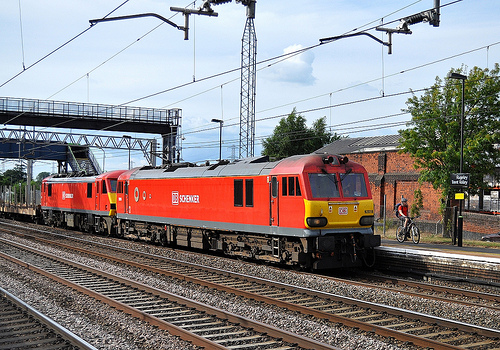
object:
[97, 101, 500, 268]
train station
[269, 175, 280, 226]
door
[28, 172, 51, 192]
tree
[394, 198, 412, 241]
bicycler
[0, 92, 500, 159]
powerlines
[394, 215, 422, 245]
biking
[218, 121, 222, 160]
pole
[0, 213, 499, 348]
rails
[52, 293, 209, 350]
gravel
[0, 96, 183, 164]
bridge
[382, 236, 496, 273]
platform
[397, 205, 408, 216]
shirt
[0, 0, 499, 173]
sky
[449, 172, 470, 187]
sign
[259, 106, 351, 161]
tree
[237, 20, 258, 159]
pillar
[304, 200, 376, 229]
front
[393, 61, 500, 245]
tree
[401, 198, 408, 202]
helmet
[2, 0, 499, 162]
cables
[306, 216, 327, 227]
headlight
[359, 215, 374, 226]
headlight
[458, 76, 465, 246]
pole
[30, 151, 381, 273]
train